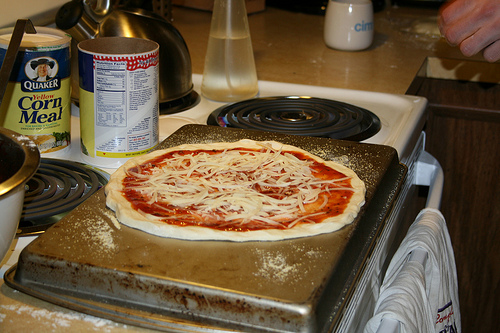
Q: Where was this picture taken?
A: The kitchen.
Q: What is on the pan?
A: A pizza.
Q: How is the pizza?
A: Uncooked.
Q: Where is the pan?
A: On the stove.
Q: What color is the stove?
A: White.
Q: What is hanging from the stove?
A: Towels.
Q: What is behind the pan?
A: Cornmeal.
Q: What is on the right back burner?
A: A kettle.